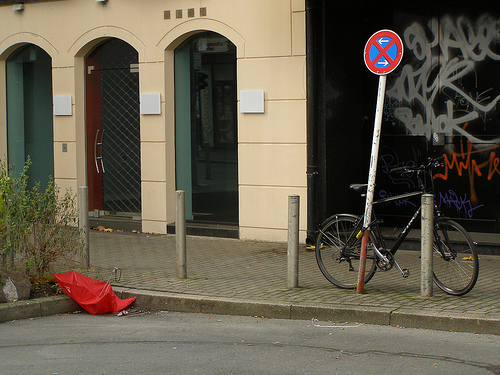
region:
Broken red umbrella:
[50, 263, 133, 313]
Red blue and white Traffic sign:
[362, 27, 397, 72]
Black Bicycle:
[312, 150, 477, 295]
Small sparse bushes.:
[2, 165, 77, 288]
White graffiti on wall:
[400, 15, 495, 150]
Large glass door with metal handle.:
[82, 64, 140, 233]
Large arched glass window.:
[160, 30, 240, 235]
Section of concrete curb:
[150, 285, 290, 325]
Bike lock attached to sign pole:
[341, 210, 381, 240]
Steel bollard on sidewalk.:
[158, 181, 194, 277]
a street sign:
[350, 23, 404, 293]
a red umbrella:
[50, 261, 141, 316]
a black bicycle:
[314, 155, 481, 298]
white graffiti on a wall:
[398, 11, 498, 148]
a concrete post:
[286, 191, 302, 291]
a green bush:
[0, 158, 82, 271]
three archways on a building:
[0, 16, 258, 238]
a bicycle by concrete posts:
[278, 153, 483, 305]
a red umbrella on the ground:
[50, 258, 157, 335]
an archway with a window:
[153, 18, 263, 240]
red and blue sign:
[350, 23, 417, 91]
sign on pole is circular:
[365, 20, 422, 87]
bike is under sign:
[318, 186, 483, 289]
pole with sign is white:
[366, 74, 402, 218]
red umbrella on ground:
[61, 250, 143, 329]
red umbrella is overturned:
[50, 244, 132, 311]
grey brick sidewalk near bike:
[175, 247, 365, 320]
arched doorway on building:
[73, 35, 157, 224]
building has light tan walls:
[140, 21, 301, 238]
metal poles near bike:
[162, 188, 307, 294]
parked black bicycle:
[313, 156, 479, 297]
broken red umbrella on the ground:
[53, 261, 135, 316]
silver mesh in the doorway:
[97, 40, 139, 212]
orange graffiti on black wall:
[430, 123, 497, 200]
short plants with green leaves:
[0, 153, 85, 295]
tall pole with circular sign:
[353, 26, 403, 291]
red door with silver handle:
[86, 57, 106, 213]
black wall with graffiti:
[309, 4, 496, 226]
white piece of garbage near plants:
[3, 277, 20, 303]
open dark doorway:
[188, 36, 237, 224]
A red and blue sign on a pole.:
[351, 28, 405, 296]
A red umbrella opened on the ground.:
[49, 260, 139, 317]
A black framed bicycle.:
[312, 157, 479, 303]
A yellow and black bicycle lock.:
[354, 217, 379, 239]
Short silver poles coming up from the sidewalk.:
[74, 183, 442, 300]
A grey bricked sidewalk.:
[1, 210, 495, 326]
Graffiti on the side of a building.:
[366, 15, 498, 219]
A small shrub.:
[4, 158, 82, 295]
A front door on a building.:
[84, 65, 149, 232]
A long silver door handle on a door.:
[89, 125, 111, 180]